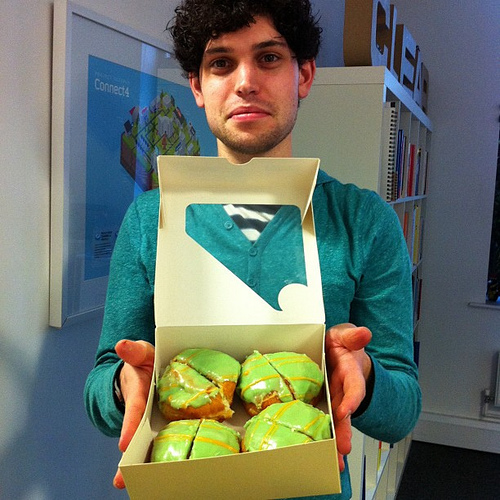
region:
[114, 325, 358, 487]
four donuts cut in half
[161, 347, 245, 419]
green and yellow frosting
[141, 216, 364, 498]
a box of yummy desert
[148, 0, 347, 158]
a dark haired man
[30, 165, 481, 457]
a blue henley shirt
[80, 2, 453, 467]
a man displaying a treat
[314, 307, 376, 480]
a man's clean hand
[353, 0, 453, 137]
large decorative wooden letters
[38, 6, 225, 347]
a white picture frame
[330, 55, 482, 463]
a white book shelf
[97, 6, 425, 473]
a man is holding a box of doughnuts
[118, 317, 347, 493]
the doughnut has bright green and yello frosting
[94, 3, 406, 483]
man wearing a blue shirt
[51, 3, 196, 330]
a framed poster behind the man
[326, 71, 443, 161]
a white bookshelf behind the man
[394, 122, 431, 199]
assorted books on a shelf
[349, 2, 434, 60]
brown letter on top of a bookshelf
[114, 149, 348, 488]
a white box with pastries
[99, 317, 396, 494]
two hand holding a box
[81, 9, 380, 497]
the man has black hair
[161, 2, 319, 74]
the young man has curly hair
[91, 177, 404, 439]
the young man is wearing a green sweater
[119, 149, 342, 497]
the young man is holding a box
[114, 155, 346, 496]
the box contains pastries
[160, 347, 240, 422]
the pastry has a green topping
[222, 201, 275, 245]
the young man is wearing a striped shirt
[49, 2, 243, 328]
the picture is hanging on the wall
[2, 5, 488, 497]
the walls are painted white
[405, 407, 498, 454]
white molding is at the base of the wall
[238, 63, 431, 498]
a bookcase is behind the young man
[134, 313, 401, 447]
the donuts is in the box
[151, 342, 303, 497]
there are four donuts in the box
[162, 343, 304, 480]
the icing is green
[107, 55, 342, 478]
the man is holding the donuts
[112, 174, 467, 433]
the shirt is green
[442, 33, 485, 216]
the wall is white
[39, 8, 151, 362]
the ad is on the wall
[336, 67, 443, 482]
the shelf is white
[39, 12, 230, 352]
the frame is white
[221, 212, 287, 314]
the shirt has buttons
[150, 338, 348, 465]
the cakes are four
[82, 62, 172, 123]
conmect is written on the picture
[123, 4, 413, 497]
a man is in the photo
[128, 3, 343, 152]
the mans hair is black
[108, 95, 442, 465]
the man is wearing cothes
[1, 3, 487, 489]
the photo is clear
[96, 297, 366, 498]
the man is holding cakes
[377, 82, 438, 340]
books are in the shelf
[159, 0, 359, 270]
the man is looking at the camera